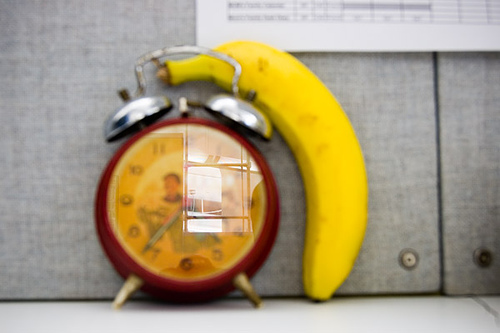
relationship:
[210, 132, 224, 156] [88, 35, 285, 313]
number on clock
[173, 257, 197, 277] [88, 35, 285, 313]
number on clock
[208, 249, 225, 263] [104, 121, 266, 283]
number on clock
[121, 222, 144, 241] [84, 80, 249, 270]
number on clock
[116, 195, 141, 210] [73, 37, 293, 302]
number on clock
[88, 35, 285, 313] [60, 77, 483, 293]
clock in photo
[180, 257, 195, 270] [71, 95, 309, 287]
number on clock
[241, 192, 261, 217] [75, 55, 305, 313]
number on clock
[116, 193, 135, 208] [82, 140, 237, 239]
number on clock